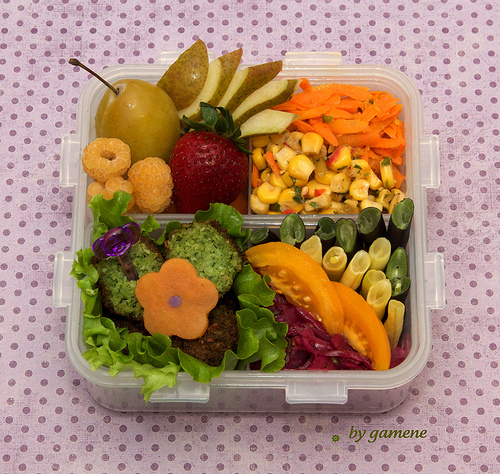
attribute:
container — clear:
[51, 51, 445, 414]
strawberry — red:
[168, 101, 253, 215]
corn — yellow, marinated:
[250, 133, 406, 216]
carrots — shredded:
[251, 79, 405, 188]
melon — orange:
[135, 257, 220, 340]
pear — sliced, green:
[157, 39, 299, 141]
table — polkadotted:
[0, 0, 499, 473]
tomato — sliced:
[245, 240, 391, 371]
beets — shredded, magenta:
[249, 264, 409, 375]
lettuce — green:
[70, 189, 289, 402]